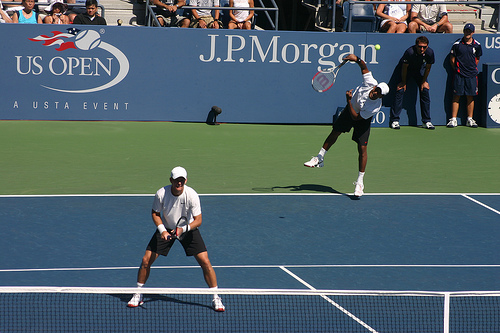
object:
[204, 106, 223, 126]
object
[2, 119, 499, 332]
court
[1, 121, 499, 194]
asphalt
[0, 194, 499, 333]
court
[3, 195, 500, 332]
asphalt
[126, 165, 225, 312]
player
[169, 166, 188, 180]
cap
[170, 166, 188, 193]
head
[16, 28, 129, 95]
logo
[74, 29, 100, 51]
ball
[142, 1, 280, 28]
railing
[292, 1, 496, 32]
railing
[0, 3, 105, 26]
railing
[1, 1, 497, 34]
stands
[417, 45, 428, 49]
sunglasses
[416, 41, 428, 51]
face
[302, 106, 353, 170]
leg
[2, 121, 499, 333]
ground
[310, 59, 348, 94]
racket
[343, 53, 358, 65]
hand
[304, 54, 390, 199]
man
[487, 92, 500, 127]
clock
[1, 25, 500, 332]
tennis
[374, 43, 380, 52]
ball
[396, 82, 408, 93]
hand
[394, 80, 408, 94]
knee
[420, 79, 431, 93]
hand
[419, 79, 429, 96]
knee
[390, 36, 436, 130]
man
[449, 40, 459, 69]
arm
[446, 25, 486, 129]
man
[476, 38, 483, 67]
arm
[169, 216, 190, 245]
racket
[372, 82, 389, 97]
hat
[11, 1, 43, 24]
woman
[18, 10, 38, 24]
top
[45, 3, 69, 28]
spectator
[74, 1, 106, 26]
spectator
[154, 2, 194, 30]
spectator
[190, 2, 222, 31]
spectator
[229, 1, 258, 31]
spectator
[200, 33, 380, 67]
sign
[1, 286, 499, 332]
net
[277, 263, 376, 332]
white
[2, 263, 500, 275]
white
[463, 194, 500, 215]
white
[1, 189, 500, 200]
white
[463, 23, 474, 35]
cap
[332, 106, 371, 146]
shorts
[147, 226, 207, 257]
shorts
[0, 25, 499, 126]
wall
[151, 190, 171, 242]
arm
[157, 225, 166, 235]
band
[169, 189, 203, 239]
arm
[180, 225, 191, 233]
band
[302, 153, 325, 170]
shoe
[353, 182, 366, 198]
shoe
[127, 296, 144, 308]
shoe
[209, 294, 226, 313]
shoe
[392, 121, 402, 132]
shoe